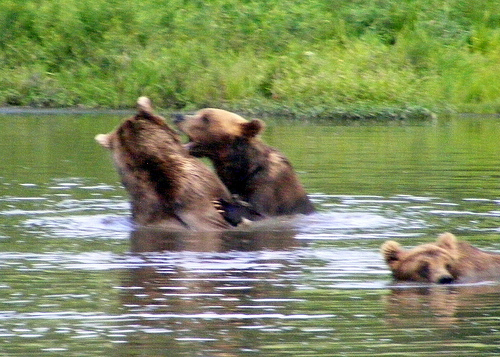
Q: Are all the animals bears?
A: Yes, all the animals are bears.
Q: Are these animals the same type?
A: Yes, all the animals are bears.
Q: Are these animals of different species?
A: No, all the animals are bears.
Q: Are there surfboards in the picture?
A: No, there are no surfboards.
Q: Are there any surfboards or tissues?
A: No, there are no surfboards or tissues.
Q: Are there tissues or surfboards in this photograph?
A: No, there are no surfboards or tissues.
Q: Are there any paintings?
A: No, there are no paintings.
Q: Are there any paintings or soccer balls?
A: No, there are no paintings or soccer balls.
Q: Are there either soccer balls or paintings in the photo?
A: No, there are no paintings or soccer balls.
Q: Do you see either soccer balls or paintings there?
A: No, there are no paintings or soccer balls.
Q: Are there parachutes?
A: No, there are no parachutes.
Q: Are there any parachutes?
A: No, there are no parachutes.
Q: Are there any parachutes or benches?
A: No, there are no parachutes or benches.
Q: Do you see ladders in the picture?
A: No, there are no ladders.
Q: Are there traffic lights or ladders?
A: No, there are no ladders or traffic lights.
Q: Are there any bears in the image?
A: Yes, there is a bear.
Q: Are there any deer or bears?
A: Yes, there is a bear.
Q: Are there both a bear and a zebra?
A: No, there is a bear but no zebras.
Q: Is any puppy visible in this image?
A: No, there are no puppies.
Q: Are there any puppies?
A: No, there are no puppies.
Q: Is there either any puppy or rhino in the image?
A: No, there are no puppies or rhinos.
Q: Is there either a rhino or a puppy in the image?
A: No, there are no puppies or rhinos.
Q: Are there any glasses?
A: No, there are no glasses.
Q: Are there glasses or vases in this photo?
A: No, there are no glasses or vases.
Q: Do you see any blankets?
A: No, there are no blankets.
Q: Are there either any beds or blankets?
A: No, there are no blankets or beds.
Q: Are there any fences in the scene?
A: No, there are no fences.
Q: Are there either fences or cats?
A: No, there are no fences or cats.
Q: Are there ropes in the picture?
A: No, there are no ropes.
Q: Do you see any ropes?
A: No, there are no ropes.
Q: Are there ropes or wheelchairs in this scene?
A: No, there are no ropes or wheelchairs.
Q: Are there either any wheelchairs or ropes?
A: No, there are no ropes or wheelchairs.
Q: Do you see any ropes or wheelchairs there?
A: No, there are no ropes or wheelchairs.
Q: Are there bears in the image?
A: Yes, there is a bear.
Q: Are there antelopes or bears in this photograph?
A: Yes, there is a bear.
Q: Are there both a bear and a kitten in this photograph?
A: No, there is a bear but no kittens.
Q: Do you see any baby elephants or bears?
A: Yes, there is a baby bear.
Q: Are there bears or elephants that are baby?
A: Yes, the bear is a baby.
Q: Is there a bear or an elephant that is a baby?
A: Yes, the bear is a baby.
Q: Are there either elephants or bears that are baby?
A: Yes, the bear is a baby.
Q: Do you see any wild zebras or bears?
A: Yes, there is a wild bear.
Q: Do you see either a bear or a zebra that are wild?
A: Yes, the bear is wild.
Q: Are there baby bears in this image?
A: Yes, there is a baby bear.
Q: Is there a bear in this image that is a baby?
A: Yes, there is a bear that is a baby.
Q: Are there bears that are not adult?
A: Yes, there is an baby bear.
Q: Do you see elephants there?
A: No, there are no elephants.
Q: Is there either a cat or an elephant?
A: No, there are no elephants or cats.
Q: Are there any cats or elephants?
A: No, there are no elephants or cats.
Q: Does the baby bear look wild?
A: Yes, the bear is wild.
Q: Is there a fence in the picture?
A: No, there are no fences.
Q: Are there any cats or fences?
A: No, there are no fences or cats.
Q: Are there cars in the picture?
A: No, there are no cars.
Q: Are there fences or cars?
A: No, there are no cars or fences.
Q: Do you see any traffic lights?
A: No, there are no traffic lights.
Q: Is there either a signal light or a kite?
A: No, there are no traffic lights or kites.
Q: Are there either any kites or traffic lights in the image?
A: No, there are no traffic lights or kites.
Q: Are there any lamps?
A: No, there are no lamps.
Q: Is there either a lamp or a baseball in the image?
A: No, there are no lamps or baseballs.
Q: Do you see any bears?
A: Yes, there is a bear.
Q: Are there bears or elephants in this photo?
A: Yes, there is a bear.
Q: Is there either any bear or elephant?
A: Yes, there is a bear.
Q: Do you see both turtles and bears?
A: No, there is a bear but no turtles.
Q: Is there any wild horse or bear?
A: Yes, there is a wild bear.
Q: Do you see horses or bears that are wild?
A: Yes, the bear is wild.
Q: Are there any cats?
A: No, there are no cats.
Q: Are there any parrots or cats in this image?
A: No, there are no cats or parrots.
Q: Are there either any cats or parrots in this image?
A: No, there are no cats or parrots.